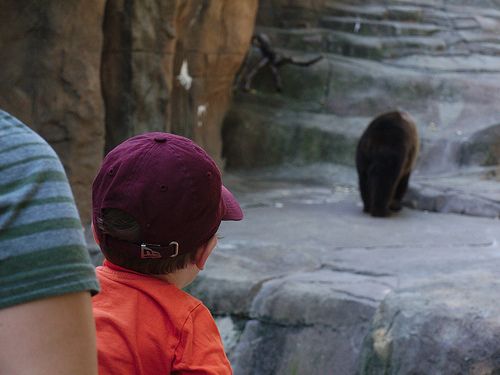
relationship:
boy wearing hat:
[91, 131, 246, 373] [89, 132, 244, 259]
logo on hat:
[140, 243, 164, 259] [89, 132, 244, 259]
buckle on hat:
[139, 242, 181, 258] [89, 132, 244, 259]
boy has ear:
[91, 131, 246, 373] [195, 233, 219, 269]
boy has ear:
[91, 131, 246, 373] [91, 222, 100, 247]